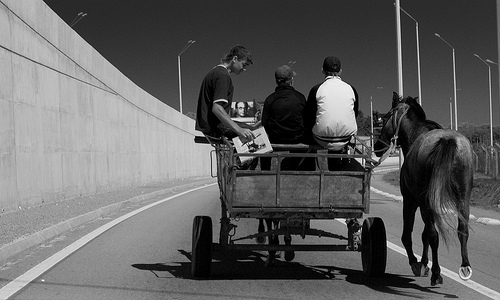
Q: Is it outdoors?
A: Yes, it is outdoors.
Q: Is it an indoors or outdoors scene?
A: It is outdoors.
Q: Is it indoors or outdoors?
A: It is outdoors.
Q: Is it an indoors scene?
A: No, it is outdoors.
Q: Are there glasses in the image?
A: No, there are no glasses.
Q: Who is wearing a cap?
A: The man is wearing a cap.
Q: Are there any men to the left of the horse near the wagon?
A: Yes, there is a man to the left of the horse.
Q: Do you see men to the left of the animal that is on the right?
A: Yes, there is a man to the left of the horse.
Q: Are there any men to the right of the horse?
A: No, the man is to the left of the horse.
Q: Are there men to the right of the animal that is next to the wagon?
A: No, the man is to the left of the horse.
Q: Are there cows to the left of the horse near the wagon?
A: No, there is a man to the left of the horse.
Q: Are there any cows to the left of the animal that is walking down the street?
A: No, there is a man to the left of the horse.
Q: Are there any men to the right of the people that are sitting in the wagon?
A: Yes, there is a man to the right of the people.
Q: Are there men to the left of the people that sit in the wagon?
A: No, the man is to the right of the people.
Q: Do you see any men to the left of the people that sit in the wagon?
A: No, the man is to the right of the people.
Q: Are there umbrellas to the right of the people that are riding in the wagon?
A: No, there is a man to the right of the people.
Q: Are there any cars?
A: No, there are no cars.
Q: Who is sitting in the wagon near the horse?
A: The people are sitting in the wagon.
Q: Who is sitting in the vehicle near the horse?
A: The people are sitting in the wagon.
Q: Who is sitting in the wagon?
A: The people are sitting in the wagon.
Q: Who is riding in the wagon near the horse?
A: The people are riding in the wagon.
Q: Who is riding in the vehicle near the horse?
A: The people are riding in the wagon.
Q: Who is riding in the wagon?
A: The people are riding in the wagon.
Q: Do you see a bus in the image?
A: No, there are no buses.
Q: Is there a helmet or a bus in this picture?
A: No, there are no buses or helmets.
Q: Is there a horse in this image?
A: Yes, there is a horse.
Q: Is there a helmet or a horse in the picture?
A: Yes, there is a horse.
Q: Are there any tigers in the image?
A: No, there are no tigers.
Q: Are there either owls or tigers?
A: No, there are no tigers or owls.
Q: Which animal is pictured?
A: The animal is a horse.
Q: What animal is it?
A: The animal is a horse.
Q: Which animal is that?
A: That is a horse.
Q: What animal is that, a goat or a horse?
A: That is a horse.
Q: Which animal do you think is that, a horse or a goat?
A: That is a horse.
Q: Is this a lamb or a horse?
A: This is a horse.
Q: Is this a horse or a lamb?
A: This is a horse.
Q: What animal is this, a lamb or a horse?
A: This is a horse.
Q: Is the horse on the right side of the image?
A: Yes, the horse is on the right of the image.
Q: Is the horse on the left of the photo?
A: No, the horse is on the right of the image.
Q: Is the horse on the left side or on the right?
A: The horse is on the right of the image.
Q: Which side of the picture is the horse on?
A: The horse is on the right of the image.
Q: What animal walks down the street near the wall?
A: The horse walks down the street.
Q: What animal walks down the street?
A: The horse walks down the street.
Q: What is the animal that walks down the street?
A: The animal is a horse.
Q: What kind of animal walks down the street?
A: The animal is a horse.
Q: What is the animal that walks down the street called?
A: The animal is a horse.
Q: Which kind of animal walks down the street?
A: The animal is a horse.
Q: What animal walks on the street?
A: The horse walks on the street.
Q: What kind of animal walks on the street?
A: The animal is a horse.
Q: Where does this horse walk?
A: The horse walks on the street.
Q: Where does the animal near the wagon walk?
A: The horse walks on the street.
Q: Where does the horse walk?
A: The horse walks on the street.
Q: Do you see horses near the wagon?
A: Yes, there is a horse near the wagon.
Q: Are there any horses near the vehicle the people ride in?
A: Yes, there is a horse near the wagon.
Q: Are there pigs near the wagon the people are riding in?
A: No, there is a horse near the wagon.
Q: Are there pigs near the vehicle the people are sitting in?
A: No, there is a horse near the wagon.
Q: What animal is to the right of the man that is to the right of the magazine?
A: The animal is a horse.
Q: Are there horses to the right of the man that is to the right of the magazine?
A: Yes, there is a horse to the right of the man.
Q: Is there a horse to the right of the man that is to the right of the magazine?
A: Yes, there is a horse to the right of the man.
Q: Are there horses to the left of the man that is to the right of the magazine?
A: No, the horse is to the right of the man.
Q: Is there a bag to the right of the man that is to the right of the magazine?
A: No, there is a horse to the right of the man.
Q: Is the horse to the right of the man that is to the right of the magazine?
A: Yes, the horse is to the right of the man.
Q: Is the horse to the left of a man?
A: No, the horse is to the right of a man.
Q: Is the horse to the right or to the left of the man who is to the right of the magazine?
A: The horse is to the right of the man.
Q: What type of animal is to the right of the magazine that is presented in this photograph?
A: The animal is a horse.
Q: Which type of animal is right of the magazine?
A: The animal is a horse.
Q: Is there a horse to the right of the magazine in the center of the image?
A: Yes, there is a horse to the right of the magazine.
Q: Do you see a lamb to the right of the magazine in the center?
A: No, there is a horse to the right of the magazine.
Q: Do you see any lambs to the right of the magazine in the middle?
A: No, there is a horse to the right of the magazine.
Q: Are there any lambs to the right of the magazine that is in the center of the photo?
A: No, there is a horse to the right of the magazine.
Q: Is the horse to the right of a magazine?
A: Yes, the horse is to the right of a magazine.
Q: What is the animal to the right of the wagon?
A: The animal is a horse.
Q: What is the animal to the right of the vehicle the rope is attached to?
A: The animal is a horse.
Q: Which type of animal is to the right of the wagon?
A: The animal is a horse.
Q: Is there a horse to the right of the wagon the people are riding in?
A: Yes, there is a horse to the right of the wagon.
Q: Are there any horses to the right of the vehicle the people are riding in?
A: Yes, there is a horse to the right of the wagon.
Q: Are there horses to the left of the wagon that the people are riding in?
A: No, the horse is to the right of the wagon.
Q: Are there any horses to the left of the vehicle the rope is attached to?
A: No, the horse is to the right of the wagon.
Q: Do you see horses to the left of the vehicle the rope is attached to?
A: No, the horse is to the right of the wagon.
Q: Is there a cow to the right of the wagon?
A: No, there is a horse to the right of the wagon.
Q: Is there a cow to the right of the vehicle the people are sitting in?
A: No, there is a horse to the right of the wagon.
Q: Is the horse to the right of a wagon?
A: Yes, the horse is to the right of a wagon.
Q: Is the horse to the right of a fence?
A: No, the horse is to the right of a wagon.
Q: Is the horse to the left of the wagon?
A: No, the horse is to the right of the wagon.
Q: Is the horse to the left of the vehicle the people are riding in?
A: No, the horse is to the right of the wagon.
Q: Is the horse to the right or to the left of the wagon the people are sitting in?
A: The horse is to the right of the wagon.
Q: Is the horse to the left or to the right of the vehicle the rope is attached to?
A: The horse is to the right of the wagon.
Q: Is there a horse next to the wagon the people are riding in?
A: Yes, there is a horse next to the wagon.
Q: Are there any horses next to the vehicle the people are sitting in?
A: Yes, there is a horse next to the wagon.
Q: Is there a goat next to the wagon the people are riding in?
A: No, there is a horse next to the wagon.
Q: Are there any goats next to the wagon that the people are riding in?
A: No, there is a horse next to the wagon.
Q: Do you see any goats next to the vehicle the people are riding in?
A: No, there is a horse next to the wagon.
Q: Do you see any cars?
A: No, there are no cars.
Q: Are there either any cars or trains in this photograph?
A: No, there are no cars or trains.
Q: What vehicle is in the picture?
A: The vehicle is a wagon.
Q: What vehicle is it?
A: The vehicle is a wagon.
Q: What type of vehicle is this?
A: That is a wagon.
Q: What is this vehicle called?
A: That is a wagon.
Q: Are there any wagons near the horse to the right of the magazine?
A: Yes, there is a wagon near the horse.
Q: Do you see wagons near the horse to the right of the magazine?
A: Yes, there is a wagon near the horse.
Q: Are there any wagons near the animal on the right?
A: Yes, there is a wagon near the horse.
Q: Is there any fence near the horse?
A: No, there is a wagon near the horse.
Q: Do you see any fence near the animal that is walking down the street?
A: No, there is a wagon near the horse.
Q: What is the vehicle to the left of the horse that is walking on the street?
A: The vehicle is a wagon.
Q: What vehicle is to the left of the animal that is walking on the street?
A: The vehicle is a wagon.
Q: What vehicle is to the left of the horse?
A: The vehicle is a wagon.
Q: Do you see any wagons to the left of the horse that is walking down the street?
A: Yes, there is a wagon to the left of the horse.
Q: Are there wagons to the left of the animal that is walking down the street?
A: Yes, there is a wagon to the left of the horse.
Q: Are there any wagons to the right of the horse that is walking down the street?
A: No, the wagon is to the left of the horse.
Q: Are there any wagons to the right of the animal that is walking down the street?
A: No, the wagon is to the left of the horse.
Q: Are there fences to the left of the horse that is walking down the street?
A: No, there is a wagon to the left of the horse.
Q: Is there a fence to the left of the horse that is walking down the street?
A: No, there is a wagon to the left of the horse.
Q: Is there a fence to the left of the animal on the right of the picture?
A: No, there is a wagon to the left of the horse.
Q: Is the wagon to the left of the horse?
A: Yes, the wagon is to the left of the horse.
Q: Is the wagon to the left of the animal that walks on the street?
A: Yes, the wagon is to the left of the horse.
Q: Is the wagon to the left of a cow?
A: No, the wagon is to the left of the horse.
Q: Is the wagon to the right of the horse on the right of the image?
A: No, the wagon is to the left of the horse.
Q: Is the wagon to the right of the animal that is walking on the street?
A: No, the wagon is to the left of the horse.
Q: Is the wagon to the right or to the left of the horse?
A: The wagon is to the left of the horse.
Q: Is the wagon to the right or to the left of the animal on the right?
A: The wagon is to the left of the horse.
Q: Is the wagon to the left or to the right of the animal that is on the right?
A: The wagon is to the left of the horse.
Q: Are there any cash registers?
A: No, there are no cash registers.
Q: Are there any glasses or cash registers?
A: No, there are no cash registers or glasses.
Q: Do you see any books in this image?
A: No, there are no books.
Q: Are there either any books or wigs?
A: No, there are no books or wigs.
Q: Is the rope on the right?
A: Yes, the rope is on the right of the image.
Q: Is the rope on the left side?
A: No, the rope is on the right of the image.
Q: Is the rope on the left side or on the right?
A: The rope is on the right of the image.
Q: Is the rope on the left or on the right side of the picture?
A: The rope is on the right of the image.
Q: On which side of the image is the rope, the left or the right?
A: The rope is on the right of the image.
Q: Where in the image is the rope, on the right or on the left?
A: The rope is on the right of the image.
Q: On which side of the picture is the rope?
A: The rope is on the right of the image.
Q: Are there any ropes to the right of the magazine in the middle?
A: Yes, there is a rope to the right of the magazine.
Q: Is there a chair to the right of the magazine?
A: No, there is a rope to the right of the magazine.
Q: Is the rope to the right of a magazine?
A: Yes, the rope is to the right of a magazine.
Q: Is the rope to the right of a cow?
A: No, the rope is to the right of a magazine.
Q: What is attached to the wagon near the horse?
A: The rope is attached to the wagon.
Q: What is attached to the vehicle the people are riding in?
A: The rope is attached to the wagon.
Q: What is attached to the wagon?
A: The rope is attached to the wagon.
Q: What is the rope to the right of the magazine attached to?
A: The rope is attached to the wagon.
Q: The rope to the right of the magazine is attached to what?
A: The rope is attached to the wagon.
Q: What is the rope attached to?
A: The rope is attached to the wagon.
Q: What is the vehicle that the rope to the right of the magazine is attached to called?
A: The vehicle is a wagon.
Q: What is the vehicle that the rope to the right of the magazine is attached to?
A: The vehicle is a wagon.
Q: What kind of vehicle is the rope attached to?
A: The rope is attached to the wagon.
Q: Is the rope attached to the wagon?
A: Yes, the rope is attached to the wagon.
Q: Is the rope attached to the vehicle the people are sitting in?
A: Yes, the rope is attached to the wagon.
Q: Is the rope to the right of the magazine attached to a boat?
A: No, the rope is attached to the wagon.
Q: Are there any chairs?
A: No, there are no chairs.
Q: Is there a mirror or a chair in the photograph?
A: No, there are no chairs or mirrors.